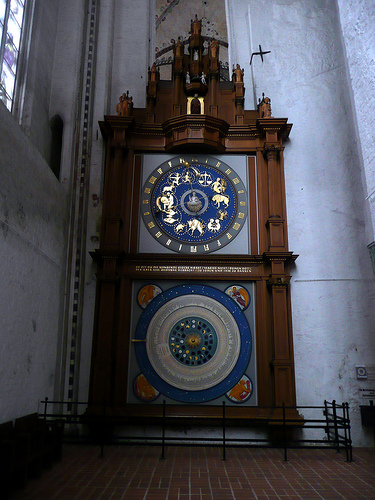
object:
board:
[111, 253, 274, 407]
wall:
[226, 0, 374, 448]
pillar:
[59, 1, 100, 421]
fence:
[36, 397, 354, 466]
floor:
[0, 441, 375, 500]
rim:
[242, 310, 253, 373]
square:
[148, 474, 163, 491]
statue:
[120, 92, 132, 116]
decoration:
[185, 217, 205, 236]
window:
[0, 0, 35, 137]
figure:
[199, 70, 208, 85]